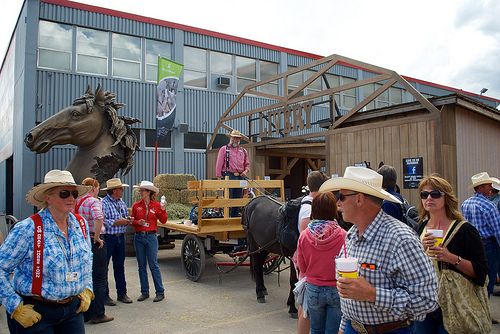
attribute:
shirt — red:
[213, 144, 248, 176]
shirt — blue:
[0, 207, 92, 316]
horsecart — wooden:
[154, 172, 286, 304]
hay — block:
[152, 174, 195, 189]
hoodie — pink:
[297, 218, 349, 285]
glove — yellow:
[75, 285, 93, 315]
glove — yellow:
[10, 300, 46, 330]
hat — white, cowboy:
[316, 165, 403, 205]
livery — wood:
[255, 100, 315, 142]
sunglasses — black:
[335, 189, 358, 200]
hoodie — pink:
[297, 221, 342, 276]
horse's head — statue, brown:
[21, 83, 143, 188]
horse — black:
[240, 196, 301, 316]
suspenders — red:
[136, 202, 156, 234]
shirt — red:
[131, 194, 160, 234]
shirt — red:
[128, 198, 168, 235]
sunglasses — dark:
[50, 188, 80, 208]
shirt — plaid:
[330, 207, 452, 320]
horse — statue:
[29, 99, 126, 182]